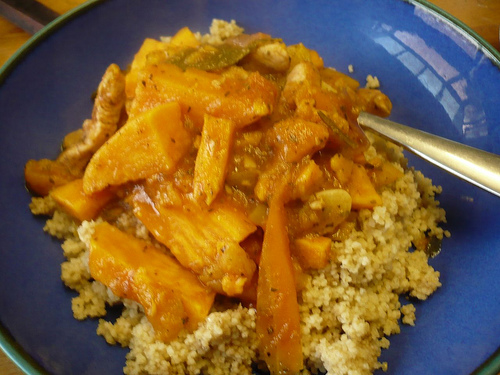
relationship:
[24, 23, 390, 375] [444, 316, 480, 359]
chicken on a plate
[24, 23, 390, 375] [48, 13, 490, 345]
chicken on plate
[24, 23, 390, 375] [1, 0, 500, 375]
chicken on blue plate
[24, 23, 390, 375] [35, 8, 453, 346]
chicken with vegetables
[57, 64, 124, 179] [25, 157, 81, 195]
ginger root next to sweet potato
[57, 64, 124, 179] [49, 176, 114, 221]
ginger root next to sweet potato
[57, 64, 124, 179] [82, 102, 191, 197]
ginger root next to sweet potato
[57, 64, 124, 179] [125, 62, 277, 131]
ginger root next to sweet potato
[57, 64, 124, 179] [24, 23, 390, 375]
ginger root next to chicken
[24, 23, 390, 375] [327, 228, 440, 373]
chicken are atop grain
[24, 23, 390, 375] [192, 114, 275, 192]
chicken in sauce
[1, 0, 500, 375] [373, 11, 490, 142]
blue plate has light reflection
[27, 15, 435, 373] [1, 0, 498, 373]
cous cous on blue plate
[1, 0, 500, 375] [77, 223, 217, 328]
blue plate made with vegetable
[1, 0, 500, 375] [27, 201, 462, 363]
blue plate made with cous cous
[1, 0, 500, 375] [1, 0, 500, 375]
blue plate on blue plate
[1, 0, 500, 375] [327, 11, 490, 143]
blue plate has light reflection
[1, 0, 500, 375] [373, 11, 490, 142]
blue plate reflects light reflection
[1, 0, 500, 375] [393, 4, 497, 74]
blue plate has trim